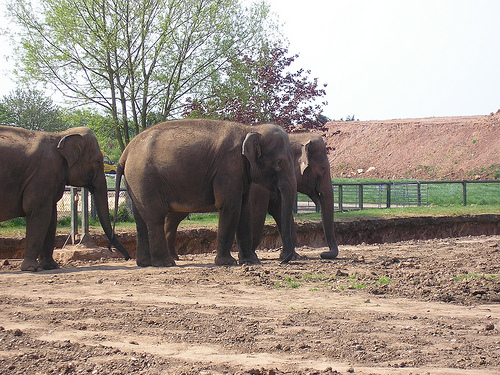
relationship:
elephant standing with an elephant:
[118, 112, 296, 264] [277, 130, 340, 264]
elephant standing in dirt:
[118, 112, 296, 264] [6, 247, 497, 374]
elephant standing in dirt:
[277, 130, 340, 264] [6, 247, 497, 374]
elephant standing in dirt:
[4, 119, 129, 269] [6, 247, 497, 374]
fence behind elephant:
[60, 181, 499, 211] [118, 112, 296, 264]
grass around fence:
[3, 176, 499, 248] [60, 181, 499, 211]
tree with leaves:
[229, 40, 340, 174] [237, 51, 321, 121]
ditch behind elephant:
[1, 205, 500, 278] [118, 112, 296, 264]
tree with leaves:
[60, 106, 134, 171] [71, 107, 122, 157]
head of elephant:
[294, 131, 336, 210] [277, 130, 340, 264]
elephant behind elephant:
[4, 119, 129, 269] [118, 112, 296, 264]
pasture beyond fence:
[1, 150, 499, 226] [60, 181, 499, 211]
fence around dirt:
[60, 181, 499, 211] [6, 247, 497, 374]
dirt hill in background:
[289, 123, 497, 176] [1, 0, 500, 188]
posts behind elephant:
[67, 184, 91, 240] [4, 119, 129, 269]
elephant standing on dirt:
[118, 112, 296, 264] [6, 247, 497, 374]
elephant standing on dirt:
[277, 130, 340, 264] [6, 247, 497, 374]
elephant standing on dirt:
[4, 119, 129, 269] [6, 247, 497, 374]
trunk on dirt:
[317, 186, 339, 260] [6, 247, 497, 374]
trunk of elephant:
[317, 186, 339, 260] [277, 130, 340, 264]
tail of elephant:
[112, 160, 123, 232] [118, 112, 296, 264]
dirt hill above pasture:
[289, 123, 497, 176] [1, 150, 499, 226]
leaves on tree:
[71, 107, 122, 157] [60, 106, 134, 171]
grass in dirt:
[282, 260, 495, 299] [6, 247, 497, 374]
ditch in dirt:
[1, 205, 500, 278] [6, 247, 497, 374]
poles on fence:
[104, 176, 498, 206] [60, 181, 499, 211]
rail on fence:
[104, 175, 498, 193] [60, 181, 499, 211]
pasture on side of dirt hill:
[1, 150, 499, 226] [289, 123, 497, 176]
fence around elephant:
[60, 181, 499, 211] [0, 125, 131, 272]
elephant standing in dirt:
[0, 125, 131, 272] [6, 247, 497, 374]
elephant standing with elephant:
[4, 119, 129, 269] [162, 135, 338, 262]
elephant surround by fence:
[0, 125, 131, 272] [60, 181, 499, 211]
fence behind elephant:
[60, 181, 499, 211] [0, 125, 131, 272]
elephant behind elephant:
[4, 119, 129, 269] [162, 135, 338, 262]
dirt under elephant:
[6, 247, 497, 374] [0, 125, 131, 272]